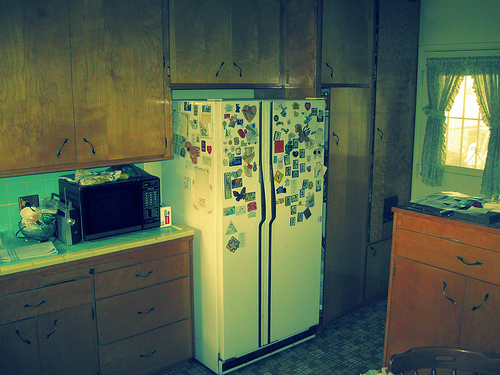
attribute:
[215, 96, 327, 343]
fridge door — white, closed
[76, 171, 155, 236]
microwave oven — black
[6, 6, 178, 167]
cabinets — closed, wooden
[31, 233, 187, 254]
countertop — green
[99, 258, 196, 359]
drawers — closed, wooden